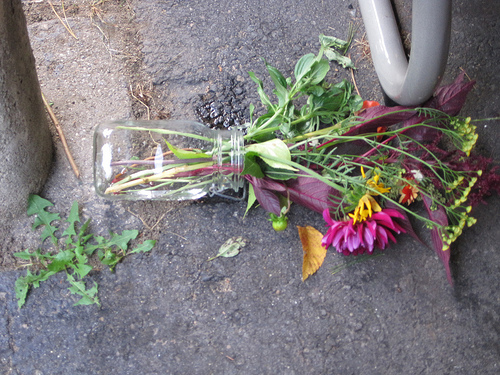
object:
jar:
[91, 114, 250, 200]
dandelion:
[0, 188, 157, 309]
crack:
[5, 193, 155, 308]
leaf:
[296, 221, 333, 281]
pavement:
[0, 0, 499, 374]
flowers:
[448, 115, 477, 159]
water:
[189, 80, 261, 133]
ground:
[1, 0, 500, 372]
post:
[0, 0, 59, 220]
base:
[0, 0, 55, 225]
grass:
[117, 31, 187, 238]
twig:
[38, 92, 85, 179]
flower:
[319, 202, 411, 257]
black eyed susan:
[348, 170, 392, 222]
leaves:
[241, 35, 374, 216]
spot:
[188, 71, 263, 131]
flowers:
[333, 165, 395, 220]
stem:
[52, 245, 83, 273]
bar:
[356, 0, 454, 106]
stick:
[38, 87, 81, 180]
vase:
[92, 118, 245, 203]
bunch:
[246, 35, 499, 292]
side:
[0, 197, 498, 375]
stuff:
[211, 218, 328, 282]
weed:
[14, 187, 156, 314]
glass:
[92, 118, 245, 201]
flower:
[353, 170, 388, 223]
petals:
[312, 202, 410, 256]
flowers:
[419, 223, 467, 251]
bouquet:
[284, 67, 499, 287]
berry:
[270, 216, 289, 230]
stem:
[278, 184, 299, 226]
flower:
[391, 181, 423, 205]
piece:
[360, 0, 450, 107]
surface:
[0, 0, 499, 375]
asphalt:
[0, 0, 496, 374]